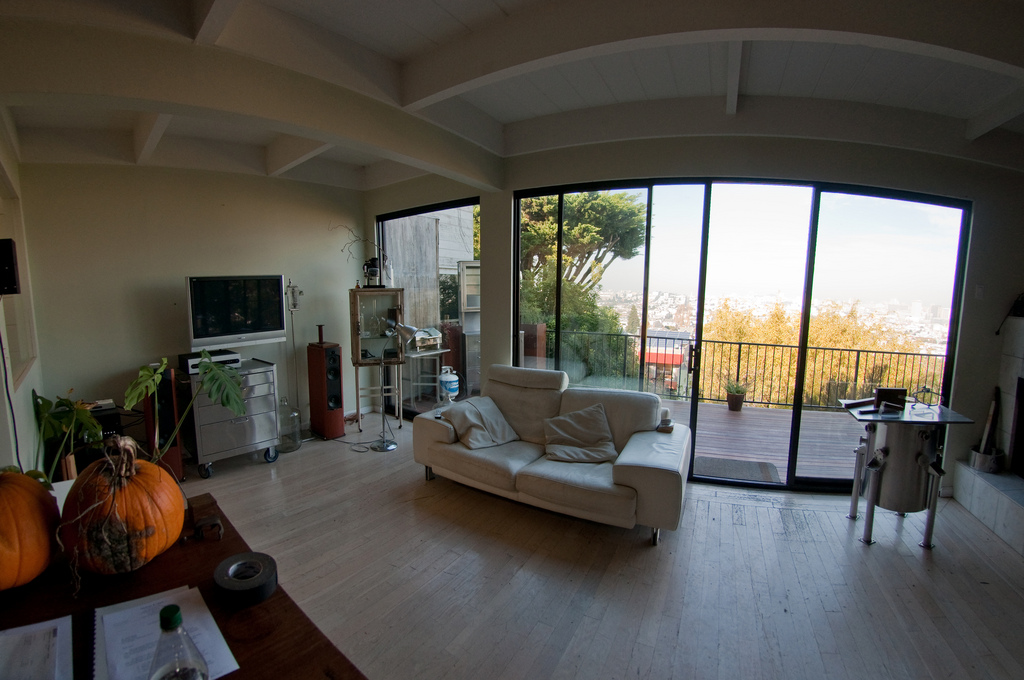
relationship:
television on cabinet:
[180, 266, 295, 354] [187, 351, 286, 465]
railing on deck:
[539, 320, 944, 419] [523, 325, 951, 481]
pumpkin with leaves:
[50, 429, 190, 579] [31, 348, 273, 485]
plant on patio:
[718, 383, 754, 412] [519, 329, 947, 496]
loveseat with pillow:
[396, 347, 707, 560] [530, 400, 623, 470]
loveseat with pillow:
[396, 347, 707, 560] [444, 396, 525, 455]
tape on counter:
[204, 547, 279, 597] [1, 478, 384, 675]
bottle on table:
[134, 603, 222, 677] [5, 482, 384, 675]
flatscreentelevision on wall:
[162, 251, 308, 353] [12, 143, 399, 485]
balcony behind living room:
[517, 328, 958, 485] [16, 35, 995, 675]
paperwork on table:
[4, 580, 251, 670] [5, 482, 384, 675]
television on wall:
[180, 266, 295, 354] [27, 169, 406, 478]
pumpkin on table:
[50, 429, 190, 579] [5, 478, 414, 671]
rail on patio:
[538, 325, 944, 414] [489, 325, 954, 492]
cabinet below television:
[187, 358, 286, 472] [180, 258, 295, 354]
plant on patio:
[718, 368, 754, 408] [515, 288, 946, 492]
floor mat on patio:
[672, 448, 802, 503] [537, 329, 980, 496]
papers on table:
[99, 587, 248, 677] [5, 482, 384, 675]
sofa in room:
[404, 375, 689, 533] [1, 46, 1021, 671]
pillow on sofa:
[425, 385, 512, 447] [448, 392, 511, 455]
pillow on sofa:
[552, 411, 606, 453] [398, 385, 673, 499]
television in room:
[180, 266, 295, 354] [8, 128, 1014, 678]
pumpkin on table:
[50, 429, 190, 579] [0, 458, 324, 677]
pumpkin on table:
[0, 458, 65, 599] [0, 458, 394, 675]